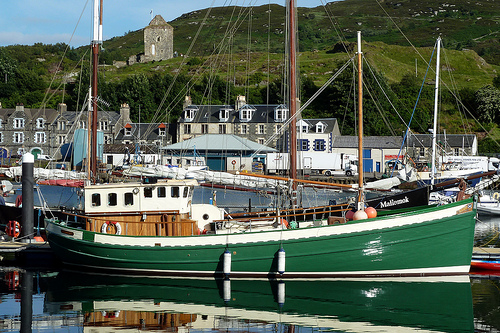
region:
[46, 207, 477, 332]
A boat with a green hull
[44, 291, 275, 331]
A reflection in the water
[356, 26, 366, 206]
A boat's mast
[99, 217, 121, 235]
A boat with a life preserver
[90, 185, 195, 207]
Ten windows in a boat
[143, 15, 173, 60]
A tower in the background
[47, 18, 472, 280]
green and white boat in the water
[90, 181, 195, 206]
windows of the boat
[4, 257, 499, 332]
water the boat is in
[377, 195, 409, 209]
white lettering on a black background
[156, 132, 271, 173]
light blue canopy in the background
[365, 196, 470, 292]
front of the green and white boat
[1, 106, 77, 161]
gray building in the background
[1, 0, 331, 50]
blue sky over the boats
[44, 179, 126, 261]
back of the green and white boat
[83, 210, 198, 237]
wood housing of the green and white boat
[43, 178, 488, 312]
the boat is green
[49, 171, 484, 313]
the boat is green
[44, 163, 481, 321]
the boat is green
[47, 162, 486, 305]
the boat is green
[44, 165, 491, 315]
the boat is green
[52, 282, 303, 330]
reflection of a boat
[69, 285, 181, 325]
reflection of a boat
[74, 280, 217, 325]
reflection of a boat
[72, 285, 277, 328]
reflection of a boat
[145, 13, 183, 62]
The castle on the hill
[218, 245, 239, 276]
The buoy to the left on the green boat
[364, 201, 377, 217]
The orange ball on the green boat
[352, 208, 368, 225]
The white ball on the green boat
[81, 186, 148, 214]
The windows on the green boat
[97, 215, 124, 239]
The life preserver on the green boat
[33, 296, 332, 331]
The reflection of the boat in the water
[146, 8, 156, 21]
The flag on the castle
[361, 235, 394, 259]
The reflection on the boat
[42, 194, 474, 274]
green and white body of a boat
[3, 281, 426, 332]
boat and cabin reflected in clear smooth water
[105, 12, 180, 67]
large stone buildings on the side of green hill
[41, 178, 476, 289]
fishing boat beside the dock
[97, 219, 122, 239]
life buoy hanging on fishing boat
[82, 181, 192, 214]
cabin on fishing boat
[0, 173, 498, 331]
body of water full of boats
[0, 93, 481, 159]
old buildings beside body of water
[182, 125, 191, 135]
one window in old building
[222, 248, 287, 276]
two weights attached to boat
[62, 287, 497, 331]
boat reflection on top of water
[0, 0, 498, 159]
scenic mountain background covered in greenery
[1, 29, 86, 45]
white clouds in blue sky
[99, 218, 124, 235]
Life ring on the boat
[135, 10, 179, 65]
gray structure on the hill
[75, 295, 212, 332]
reflection of boat on the water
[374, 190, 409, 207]
white lettering on the boat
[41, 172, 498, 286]
boat on the water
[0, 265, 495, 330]
water covering the surface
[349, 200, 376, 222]
buoys on the boat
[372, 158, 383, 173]
blue door in the building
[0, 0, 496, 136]
green grass covering the surface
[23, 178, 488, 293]
a green boat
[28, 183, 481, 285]
a green and white boat